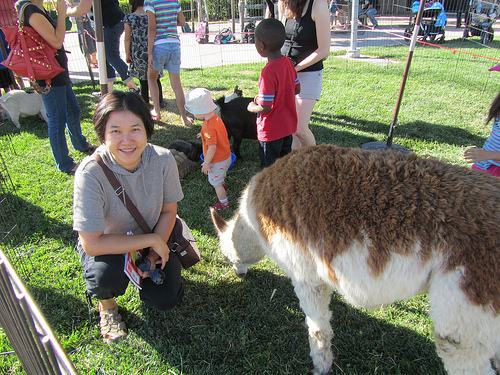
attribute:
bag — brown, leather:
[174, 212, 206, 248]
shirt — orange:
[203, 112, 232, 153]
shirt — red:
[256, 65, 288, 120]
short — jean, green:
[67, 261, 134, 303]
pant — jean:
[150, 271, 186, 299]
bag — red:
[11, 42, 48, 68]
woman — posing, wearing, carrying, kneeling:
[61, 60, 218, 331]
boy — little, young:
[181, 80, 249, 192]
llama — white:
[208, 137, 378, 308]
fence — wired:
[233, 3, 260, 18]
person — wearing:
[69, 94, 194, 269]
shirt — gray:
[97, 175, 176, 232]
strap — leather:
[111, 184, 149, 223]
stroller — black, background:
[216, 105, 261, 146]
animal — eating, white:
[211, 179, 295, 305]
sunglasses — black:
[135, 255, 165, 290]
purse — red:
[11, 33, 44, 74]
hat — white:
[182, 74, 223, 109]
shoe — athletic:
[79, 301, 142, 357]